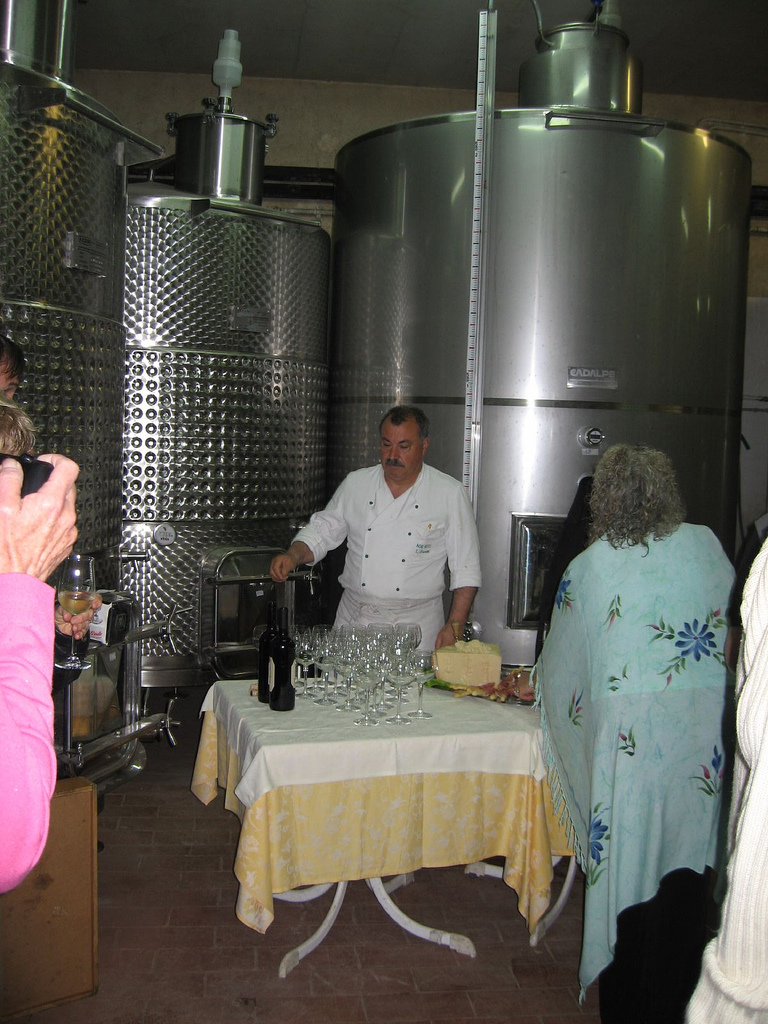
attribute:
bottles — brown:
[253, 585, 306, 710]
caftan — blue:
[603, 565, 674, 641]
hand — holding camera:
[2, 449, 81, 574]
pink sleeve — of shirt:
[3, 566, 61, 892]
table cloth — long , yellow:
[195, 707, 581, 937]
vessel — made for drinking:
[357, 657, 386, 725]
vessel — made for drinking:
[410, 649, 430, 723]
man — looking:
[259, 364, 510, 735]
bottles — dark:
[249, 606, 300, 717]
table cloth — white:
[185, 649, 575, 915]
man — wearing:
[256, 393, 483, 684]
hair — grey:
[576, 423, 687, 579]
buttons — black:
[398, 492, 430, 605]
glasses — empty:
[296, 587, 476, 754]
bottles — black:
[232, 571, 312, 774]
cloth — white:
[193, 659, 563, 805]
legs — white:
[239, 860, 468, 1024]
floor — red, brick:
[98, 698, 607, 1024]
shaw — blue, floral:
[521, 498, 720, 981]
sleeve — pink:
[9, 566, 92, 894]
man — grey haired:
[224, 371, 511, 678]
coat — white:
[275, 459, 478, 632]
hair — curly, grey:
[587, 427, 686, 556]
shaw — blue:
[527, 559, 739, 990]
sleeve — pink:
[2, 565, 62, 925]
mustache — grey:
[379, 453, 409, 475]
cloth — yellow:
[186, 712, 578, 954]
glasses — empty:
[291, 617, 441, 759]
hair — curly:
[576, 438, 698, 556]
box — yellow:
[13, 770, 105, 1021]